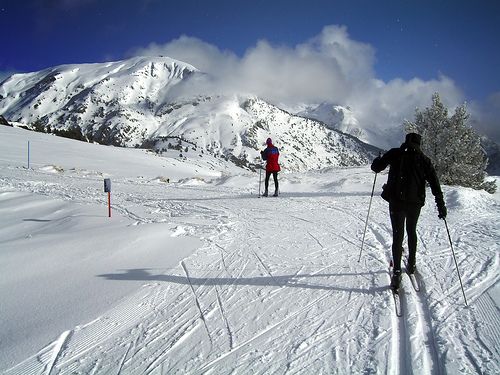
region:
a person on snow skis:
[358, 109, 449, 337]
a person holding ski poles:
[370, 114, 470, 307]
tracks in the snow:
[132, 207, 352, 367]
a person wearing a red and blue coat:
[239, 128, 291, 214]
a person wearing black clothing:
[352, 118, 437, 306]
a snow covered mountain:
[0, 39, 238, 163]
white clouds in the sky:
[182, 49, 367, 105]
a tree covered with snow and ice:
[419, 90, 489, 200]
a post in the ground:
[94, 160, 124, 222]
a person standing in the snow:
[254, 131, 286, 218]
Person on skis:
[386, 248, 425, 317]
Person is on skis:
[382, 248, 422, 318]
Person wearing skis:
[381, 247, 428, 321]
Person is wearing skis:
[382, 251, 424, 320]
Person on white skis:
[384, 240, 424, 321]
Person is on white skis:
[385, 242, 422, 319]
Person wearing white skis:
[385, 241, 424, 323]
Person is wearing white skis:
[387, 242, 420, 317]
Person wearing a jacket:
[370, 141, 444, 208]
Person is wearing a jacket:
[368, 141, 443, 206]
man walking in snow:
[357, 113, 442, 290]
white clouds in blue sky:
[7, 18, 67, 49]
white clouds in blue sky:
[84, 25, 146, 86]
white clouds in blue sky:
[178, 23, 229, 63]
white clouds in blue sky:
[235, 29, 259, 46]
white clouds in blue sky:
[232, 28, 286, 78]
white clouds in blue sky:
[287, 39, 322, 74]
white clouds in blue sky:
[308, 45, 356, 95]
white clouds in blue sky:
[360, 35, 398, 77]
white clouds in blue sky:
[385, 2, 442, 93]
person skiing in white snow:
[371, 118, 445, 300]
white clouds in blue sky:
[88, 15, 175, 53]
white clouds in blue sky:
[15, 28, 76, 60]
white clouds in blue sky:
[305, 82, 339, 97]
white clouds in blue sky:
[410, 38, 461, 66]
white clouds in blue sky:
[351, 32, 388, 66]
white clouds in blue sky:
[271, 82, 342, 96]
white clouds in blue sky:
[331, 61, 382, 103]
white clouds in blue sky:
[377, 35, 434, 79]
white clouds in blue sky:
[320, 5, 385, 65]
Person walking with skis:
[351, 125, 471, 309]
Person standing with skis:
[251, 127, 291, 197]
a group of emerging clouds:
[146, 23, 497, 140]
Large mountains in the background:
[1, 55, 383, 159]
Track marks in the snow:
[364, 219, 445, 373]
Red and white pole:
[101, 175, 116, 215]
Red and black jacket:
[256, 143, 284, 174]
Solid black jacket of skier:
[363, 140, 453, 215]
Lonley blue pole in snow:
[21, 135, 33, 170]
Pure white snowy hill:
[5, 125, 497, 372]